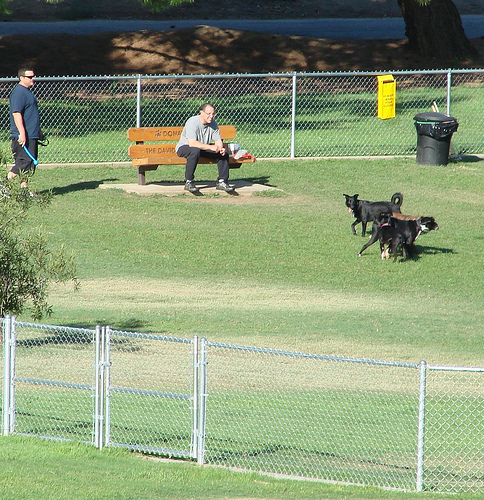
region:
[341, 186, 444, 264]
dogs playing in field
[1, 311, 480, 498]
chain-link fence in foreground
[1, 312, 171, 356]
shadow of tree on grass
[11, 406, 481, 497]
shadow of fence on grass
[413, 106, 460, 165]
black trash can in front of back fence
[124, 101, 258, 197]
man sitting on wooden bench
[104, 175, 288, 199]
dirt patch under wooden bench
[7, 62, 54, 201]
standing man in black sunglasses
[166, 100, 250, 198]
sitting man's elbow on lap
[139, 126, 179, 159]
engraved letters on wooden bench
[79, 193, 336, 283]
patch of green grass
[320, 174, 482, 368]
dogs playing together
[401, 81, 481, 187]
a black trash can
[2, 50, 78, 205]
a man wearing sunglasses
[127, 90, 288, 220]
man sitting on a bench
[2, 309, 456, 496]
chain link fence and gate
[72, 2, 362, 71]
shadows being cast on ground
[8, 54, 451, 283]
owners watching their dogs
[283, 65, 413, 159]
yellow container hanging on fence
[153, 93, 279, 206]
man wearing black pants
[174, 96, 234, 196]
Man wearing a gray shirt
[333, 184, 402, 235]
Black dog on the grass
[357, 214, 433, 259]
Black dog on the grass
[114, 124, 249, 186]
Wood bench under the man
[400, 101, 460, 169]
Trash can near the gate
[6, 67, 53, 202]
Man wearing a blue shirt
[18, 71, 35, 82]
Sunglasses on man's face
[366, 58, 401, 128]
Yellow bin on the gate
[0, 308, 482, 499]
Metal fence on the grass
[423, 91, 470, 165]
Broom on side of dustpan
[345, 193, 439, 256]
dogs standing next to each other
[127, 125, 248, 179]
a wooden bench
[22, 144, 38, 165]
a blue ball tosser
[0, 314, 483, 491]
metal chain link fence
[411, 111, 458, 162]
black plastic trash can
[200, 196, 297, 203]
patch of dirt in the grass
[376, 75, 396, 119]
yellow box on the fence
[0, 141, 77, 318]
green leaves on a tree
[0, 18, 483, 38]
a concrete sidewalk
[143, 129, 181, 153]
engravings on the bench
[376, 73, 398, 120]
yellow dog-scoop bag dispenser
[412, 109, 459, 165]
black plastic trash bin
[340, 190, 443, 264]
a pack of four black-fur dogs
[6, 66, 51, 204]
man in blue shirt holding blue stick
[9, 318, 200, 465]
chain-link gate with lock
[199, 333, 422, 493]
section of chain-link fence adjacent to gate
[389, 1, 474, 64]
large tree trunk in background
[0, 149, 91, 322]
branches of a smaller tree within the fence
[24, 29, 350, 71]
mound of dirt behind fence